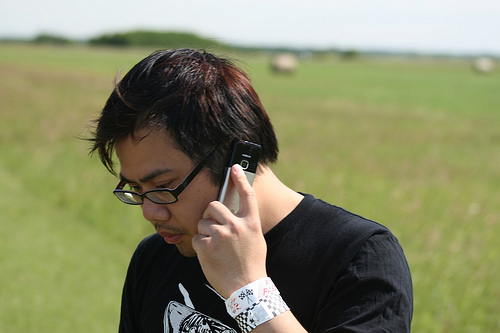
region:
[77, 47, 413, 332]
man talking on cell phone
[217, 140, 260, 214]
a black and gray cell phone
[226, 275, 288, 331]
bracelets on the man's wrist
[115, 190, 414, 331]
a t-shirt on the man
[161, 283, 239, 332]
white drawing on the t-shirt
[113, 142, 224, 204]
black glasses on the man's face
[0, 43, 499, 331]
a green field behind the man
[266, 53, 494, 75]
blurry objects in field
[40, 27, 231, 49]
a green hill behind the man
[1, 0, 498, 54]
bright sky behind the man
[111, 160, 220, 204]
a man wearing black glasses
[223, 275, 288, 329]
a man wearing two bangles on his wrist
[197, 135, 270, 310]
a man holding a cellphone to his ear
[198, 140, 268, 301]
a black and silver cellphone in man's hand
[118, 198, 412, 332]
man wearing a black shirt with a white logo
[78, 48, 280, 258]
a man with black hair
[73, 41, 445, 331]
a man standing in a field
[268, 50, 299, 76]
a sheep in a field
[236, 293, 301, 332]
a checkered black and white bangle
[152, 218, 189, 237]
man with a thin mustache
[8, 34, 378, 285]
a man on a cell phone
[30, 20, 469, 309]
a man with long hair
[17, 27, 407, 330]
a man on a phone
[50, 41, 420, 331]
a man wearing glasses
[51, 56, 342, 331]
a man wearing black glasses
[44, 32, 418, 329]
a man wearing plastic frames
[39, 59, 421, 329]
a man wearing a shirt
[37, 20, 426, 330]
a man wearing a black shirt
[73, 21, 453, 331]
a man in a field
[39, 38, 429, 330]
a man standing outside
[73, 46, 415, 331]
man listening on phone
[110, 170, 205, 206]
black frame eyeglasses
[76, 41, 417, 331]
man wearing black shirt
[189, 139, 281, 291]
hand holding phone to ear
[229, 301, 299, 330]
checkered wrist band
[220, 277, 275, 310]
wristband with two checkered flags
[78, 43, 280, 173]
shiny reddish brown hair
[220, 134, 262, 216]
black and silver phone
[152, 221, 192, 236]
black mustache over lip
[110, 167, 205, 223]
eyeglasses on bridge of nose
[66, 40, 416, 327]
man with cellphone to ear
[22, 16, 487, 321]
man in front of grassy field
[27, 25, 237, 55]
low green mound on field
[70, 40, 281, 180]
dark hair lightly blowing in breeze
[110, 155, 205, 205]
black eyeglass frames with oblong lenses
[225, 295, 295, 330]
bracelet with checkerboard strap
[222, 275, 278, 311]
bracelet with black and white flags and red designs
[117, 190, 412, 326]
black t-shirt with white design on front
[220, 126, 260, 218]
pointer finger over black and silver phone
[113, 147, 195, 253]
man with head slanted forward looking down